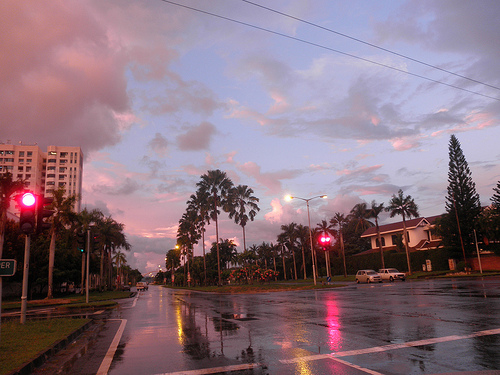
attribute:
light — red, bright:
[11, 189, 45, 217]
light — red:
[319, 231, 333, 249]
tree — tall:
[447, 135, 484, 260]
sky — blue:
[7, 4, 500, 264]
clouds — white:
[304, 52, 407, 142]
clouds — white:
[390, 5, 496, 53]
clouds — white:
[145, 77, 221, 152]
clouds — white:
[116, 193, 183, 237]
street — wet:
[30, 261, 499, 369]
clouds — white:
[420, 81, 500, 135]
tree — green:
[390, 190, 422, 224]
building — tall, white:
[47, 146, 81, 222]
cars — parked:
[351, 264, 403, 285]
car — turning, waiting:
[136, 278, 148, 292]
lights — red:
[11, 182, 334, 325]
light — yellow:
[176, 245, 182, 252]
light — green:
[167, 252, 179, 284]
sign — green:
[4, 260, 19, 272]